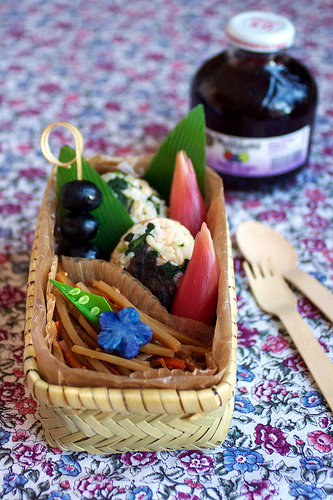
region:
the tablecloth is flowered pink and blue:
[0, 0, 331, 498]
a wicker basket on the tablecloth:
[19, 136, 239, 458]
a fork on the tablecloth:
[232, 257, 329, 413]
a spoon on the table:
[233, 215, 330, 325]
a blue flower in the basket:
[97, 308, 152, 358]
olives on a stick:
[30, 111, 104, 256]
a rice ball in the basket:
[97, 218, 199, 289]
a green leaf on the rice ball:
[121, 228, 182, 296]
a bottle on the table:
[175, 5, 316, 185]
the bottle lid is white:
[223, 12, 296, 53]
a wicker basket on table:
[19, 127, 244, 460]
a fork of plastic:
[235, 256, 297, 421]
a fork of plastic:
[238, 217, 307, 275]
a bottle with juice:
[188, 6, 331, 198]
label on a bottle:
[206, 117, 313, 183]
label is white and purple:
[202, 123, 315, 179]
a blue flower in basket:
[92, 302, 155, 366]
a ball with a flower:
[109, 213, 196, 294]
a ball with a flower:
[100, 172, 163, 221]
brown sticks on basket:
[43, 267, 212, 396]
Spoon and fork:
[236, 215, 332, 418]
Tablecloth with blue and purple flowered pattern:
[4, 3, 314, 498]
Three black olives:
[59, 178, 105, 264]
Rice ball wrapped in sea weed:
[110, 211, 189, 300]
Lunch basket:
[24, 144, 237, 450]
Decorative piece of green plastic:
[145, 99, 204, 196]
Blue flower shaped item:
[96, 307, 152, 358]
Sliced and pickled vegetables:
[52, 273, 199, 370]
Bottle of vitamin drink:
[192, 9, 315, 189]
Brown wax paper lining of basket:
[33, 154, 233, 394]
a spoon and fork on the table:
[227, 198, 314, 355]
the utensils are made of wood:
[245, 210, 323, 348]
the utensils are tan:
[244, 206, 329, 367]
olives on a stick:
[50, 167, 95, 261]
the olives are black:
[47, 177, 106, 250]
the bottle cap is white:
[216, 8, 298, 62]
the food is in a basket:
[25, 135, 247, 433]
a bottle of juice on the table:
[172, 1, 309, 184]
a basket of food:
[36, 133, 254, 444]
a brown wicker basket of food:
[7, 280, 231, 490]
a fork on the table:
[204, 223, 330, 448]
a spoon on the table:
[229, 211, 329, 338]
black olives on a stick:
[45, 116, 96, 282]